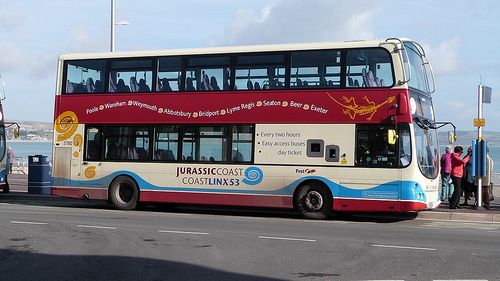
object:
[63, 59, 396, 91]
deck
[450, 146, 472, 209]
people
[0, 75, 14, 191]
bus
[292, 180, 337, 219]
front wheel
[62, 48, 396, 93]
windows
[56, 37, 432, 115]
top deck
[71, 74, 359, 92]
passenger seats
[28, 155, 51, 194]
bin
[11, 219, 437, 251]
lines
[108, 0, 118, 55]
pole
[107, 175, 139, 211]
wheel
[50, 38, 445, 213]
double-decker bus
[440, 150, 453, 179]
blue helmet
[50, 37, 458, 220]
bus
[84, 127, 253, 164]
windows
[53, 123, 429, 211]
deck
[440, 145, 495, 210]
group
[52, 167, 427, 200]
blue paint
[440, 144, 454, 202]
person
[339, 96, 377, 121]
skeleton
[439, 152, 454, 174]
jacket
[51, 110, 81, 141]
spiral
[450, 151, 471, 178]
coat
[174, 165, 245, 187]
advertisement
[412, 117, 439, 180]
windshield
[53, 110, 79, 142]
paint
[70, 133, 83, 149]
paint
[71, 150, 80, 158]
paint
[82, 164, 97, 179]
paint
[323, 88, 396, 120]
paint